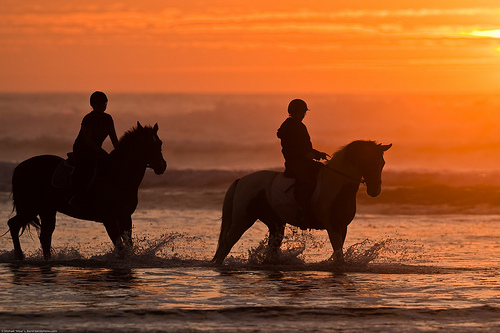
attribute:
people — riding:
[66, 82, 382, 182]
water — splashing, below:
[129, 238, 379, 313]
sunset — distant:
[229, 30, 499, 135]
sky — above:
[122, 16, 361, 123]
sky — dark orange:
[1, 3, 499, 90]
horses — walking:
[8, 108, 393, 280]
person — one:
[70, 92, 116, 154]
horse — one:
[10, 122, 167, 267]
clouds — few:
[7, 7, 493, 60]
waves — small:
[3, 127, 493, 209]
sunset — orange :
[2, 7, 495, 158]